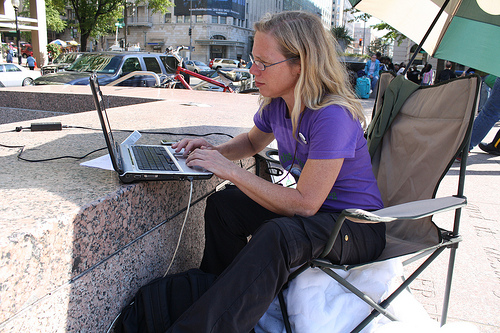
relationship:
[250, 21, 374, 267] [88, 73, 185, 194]
woman on laptop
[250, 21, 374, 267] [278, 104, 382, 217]
woman has shirt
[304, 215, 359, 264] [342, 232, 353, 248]
pocket has silver snap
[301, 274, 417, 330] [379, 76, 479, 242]
blanket under chair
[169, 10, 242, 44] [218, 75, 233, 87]
building across street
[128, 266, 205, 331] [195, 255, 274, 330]
backpack leaning leg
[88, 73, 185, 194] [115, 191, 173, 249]
laptop on wall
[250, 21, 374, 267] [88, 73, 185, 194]
woman working on laptop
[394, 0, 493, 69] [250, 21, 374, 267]
umbrella shades woman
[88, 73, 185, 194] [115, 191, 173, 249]
laptop on top of wall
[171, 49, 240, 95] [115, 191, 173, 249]
bicycle beside wall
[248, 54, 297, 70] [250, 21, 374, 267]
glasses on woman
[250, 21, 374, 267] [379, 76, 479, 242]
woman on top of chair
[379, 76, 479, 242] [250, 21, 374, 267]
chair under woman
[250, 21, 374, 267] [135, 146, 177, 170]
woman typing on keyboard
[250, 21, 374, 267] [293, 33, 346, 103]
woman has hair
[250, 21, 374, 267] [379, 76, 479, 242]
woman sits in chair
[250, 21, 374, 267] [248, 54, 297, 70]
woman has glasses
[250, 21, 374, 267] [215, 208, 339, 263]
woman has pants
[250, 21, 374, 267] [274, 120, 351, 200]
woman has arms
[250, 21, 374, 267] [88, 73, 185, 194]
woman uses laptop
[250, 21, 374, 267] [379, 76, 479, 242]
woman sitting in chair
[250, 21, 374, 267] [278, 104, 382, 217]
woman in shirt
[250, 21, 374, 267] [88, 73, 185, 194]
woman using laptop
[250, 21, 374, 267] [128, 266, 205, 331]
woman has backpack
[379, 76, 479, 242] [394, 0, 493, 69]
chair has umbrella